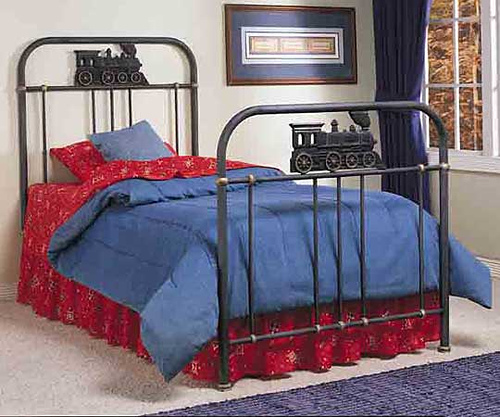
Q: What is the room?
A: A bedroom.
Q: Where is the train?
A: On the metal bed frame.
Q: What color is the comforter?
A: Blue.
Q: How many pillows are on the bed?
A: Two.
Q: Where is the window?
A: To the right of the bed.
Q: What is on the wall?
A: A picture.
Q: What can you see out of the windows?
A: Leaves.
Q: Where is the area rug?
A: In front of the bed.